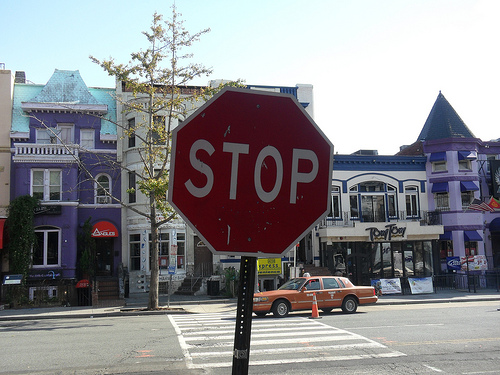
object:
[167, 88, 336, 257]
sign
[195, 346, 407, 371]
lines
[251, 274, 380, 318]
taxi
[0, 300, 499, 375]
street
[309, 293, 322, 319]
cone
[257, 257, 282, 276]
sign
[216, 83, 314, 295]
building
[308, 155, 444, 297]
building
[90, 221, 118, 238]
awning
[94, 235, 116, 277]
entrance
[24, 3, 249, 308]
tree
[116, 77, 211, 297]
building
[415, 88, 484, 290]
building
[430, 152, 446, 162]
awning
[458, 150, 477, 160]
awning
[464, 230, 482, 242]
awning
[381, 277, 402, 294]
sign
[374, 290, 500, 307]
sidewalk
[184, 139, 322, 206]
stop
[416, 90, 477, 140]
roof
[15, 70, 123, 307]
building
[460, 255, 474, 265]
sign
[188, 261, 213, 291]
fence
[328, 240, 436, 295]
storefront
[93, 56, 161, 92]
leaves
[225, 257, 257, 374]
pole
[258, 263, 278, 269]
express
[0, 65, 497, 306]
row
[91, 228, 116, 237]
designs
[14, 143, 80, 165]
balcony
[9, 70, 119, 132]
top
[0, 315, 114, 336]
shadows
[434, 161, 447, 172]
windows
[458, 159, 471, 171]
windows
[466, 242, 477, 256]
windows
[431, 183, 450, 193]
awning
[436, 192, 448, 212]
windows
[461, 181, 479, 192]
awning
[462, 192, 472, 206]
windows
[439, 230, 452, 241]
awning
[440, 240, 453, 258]
windows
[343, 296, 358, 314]
tire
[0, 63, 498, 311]
establishments